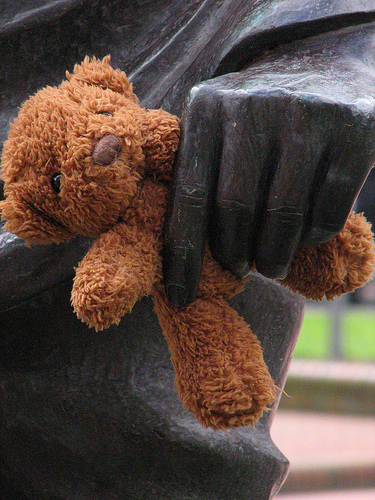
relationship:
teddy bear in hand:
[1, 57, 374, 430] [155, 30, 369, 305]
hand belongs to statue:
[155, 30, 369, 305] [1, 2, 374, 495]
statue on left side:
[1, 2, 374, 495] [2, 1, 375, 494]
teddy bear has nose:
[1, 57, 374, 430] [87, 133, 124, 168]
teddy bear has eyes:
[1, 57, 374, 430] [45, 107, 113, 193]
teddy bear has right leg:
[1, 57, 374, 430] [160, 300, 275, 430]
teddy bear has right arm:
[1, 57, 374, 430] [68, 228, 150, 332]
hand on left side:
[155, 30, 369, 305] [2, 1, 375, 494]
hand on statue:
[155, 30, 369, 305] [1, 2, 374, 495]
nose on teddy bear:
[87, 133, 124, 168] [1, 57, 374, 430]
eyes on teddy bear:
[45, 107, 113, 193] [1, 57, 374, 430]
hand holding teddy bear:
[155, 30, 369, 305] [1, 57, 374, 430]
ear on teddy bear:
[67, 53, 147, 99] [1, 57, 374, 430]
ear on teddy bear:
[0, 191, 73, 251] [1, 57, 374, 430]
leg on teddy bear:
[160, 300, 275, 430] [1, 57, 374, 430]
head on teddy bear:
[2, 48, 145, 248] [1, 57, 374, 430]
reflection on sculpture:
[214, 40, 374, 116] [1, 2, 374, 495]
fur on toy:
[5, 61, 373, 424] [1, 57, 374, 430]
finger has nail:
[162, 90, 215, 310] [165, 277, 189, 312]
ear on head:
[67, 53, 147, 99] [2, 48, 145, 248]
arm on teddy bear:
[68, 228, 150, 332] [1, 57, 374, 430]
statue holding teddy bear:
[1, 2, 374, 495] [1, 57, 374, 430]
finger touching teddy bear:
[162, 90, 215, 310] [1, 57, 374, 430]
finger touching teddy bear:
[212, 128, 259, 280] [1, 57, 374, 430]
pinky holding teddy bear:
[304, 131, 371, 258] [1, 57, 374, 430]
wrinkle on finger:
[174, 184, 208, 216] [162, 90, 215, 310]